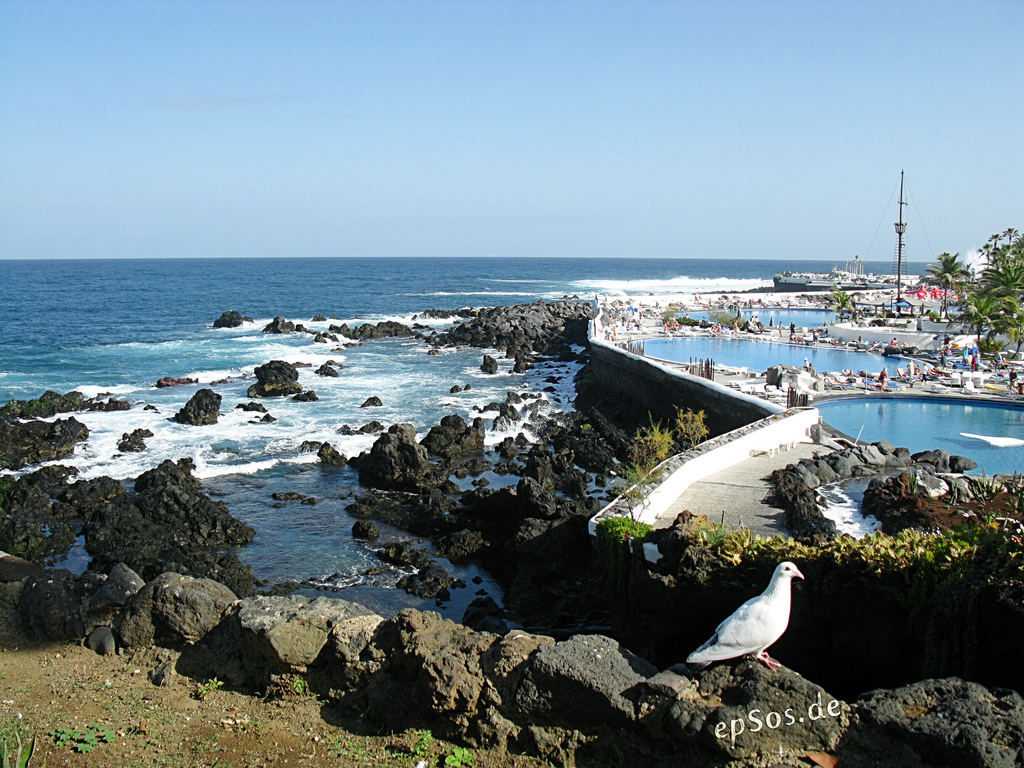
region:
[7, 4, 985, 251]
the sky is blue and clear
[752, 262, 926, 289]
the boat on the water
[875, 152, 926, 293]
the mast of a ship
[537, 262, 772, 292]
the large white wave by the boat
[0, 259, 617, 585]
the water is calm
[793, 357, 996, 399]
people by the pool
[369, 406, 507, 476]
rocks are jagged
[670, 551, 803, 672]
the bird is white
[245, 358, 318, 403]
A big rock is visible in the ocean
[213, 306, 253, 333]
A big rock is visible in the ocean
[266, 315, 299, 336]
A big rock is visible in the ocean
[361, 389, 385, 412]
A big rock is visible in the ocean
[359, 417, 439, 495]
A big rock is visible in the ocean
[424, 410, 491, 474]
A big rock is visible in the ocean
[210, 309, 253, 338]
A big rock is visible in the ocean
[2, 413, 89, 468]
A big rock is visible in the ocean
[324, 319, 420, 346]
A big rock is visible in the ocean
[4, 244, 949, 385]
a large body of water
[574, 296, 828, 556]
a cement retaining wall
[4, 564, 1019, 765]
a rock lined retaining wall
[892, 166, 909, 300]
a tall wooden crows nest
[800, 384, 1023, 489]
an in ground pool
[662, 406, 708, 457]
an ornamental trimmed bush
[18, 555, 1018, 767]
a line of dark colored rocks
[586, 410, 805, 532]
a white cement flower planter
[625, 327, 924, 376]
an in ground swimming pool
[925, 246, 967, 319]
an ornametal palm tree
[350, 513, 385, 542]
A rock in the water.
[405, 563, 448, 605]
A rock in the water.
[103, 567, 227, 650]
A rock in the water.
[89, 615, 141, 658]
A rock in the water.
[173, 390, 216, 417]
A rock in the water.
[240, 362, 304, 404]
A rock in the water.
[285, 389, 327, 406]
A rock in the water.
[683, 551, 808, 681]
White bird with red feet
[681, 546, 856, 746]
white bird standing on a grey rock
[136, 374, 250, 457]
white surf crashing against grey rocks